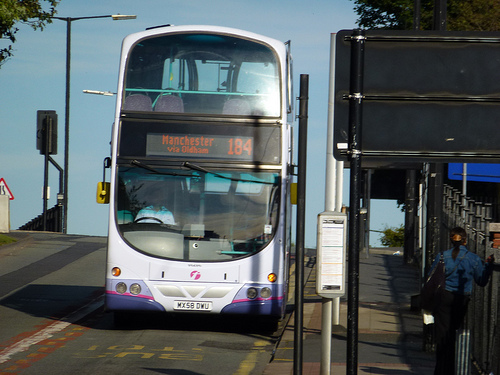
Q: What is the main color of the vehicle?
A: White.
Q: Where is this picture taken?
A: In the street.